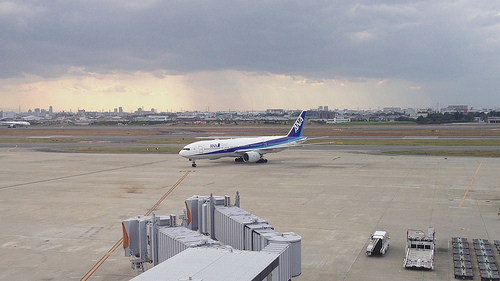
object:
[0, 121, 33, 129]
airplane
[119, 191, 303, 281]
two jettys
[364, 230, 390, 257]
vehicle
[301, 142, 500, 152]
runway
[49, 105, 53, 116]
buildings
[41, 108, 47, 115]
buildings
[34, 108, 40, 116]
buildings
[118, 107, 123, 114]
buildings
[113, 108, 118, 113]
buildings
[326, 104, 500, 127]
city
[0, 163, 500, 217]
concrete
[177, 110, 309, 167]
airplane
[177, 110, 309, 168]
plane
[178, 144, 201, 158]
windows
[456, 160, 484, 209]
line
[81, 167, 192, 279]
line